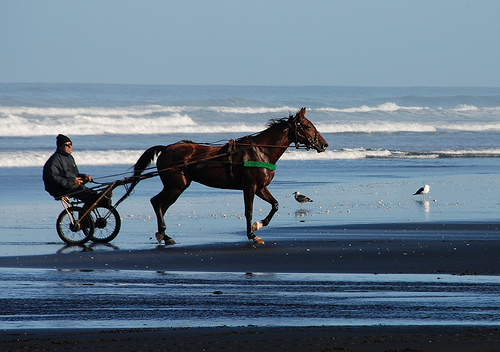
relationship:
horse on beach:
[132, 106, 330, 247] [1, 167, 499, 351]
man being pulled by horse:
[41, 132, 112, 229] [132, 106, 330, 247]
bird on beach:
[291, 190, 314, 207] [1, 167, 499, 351]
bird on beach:
[412, 182, 431, 196] [1, 167, 499, 351]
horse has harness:
[132, 106, 330, 247] [175, 114, 301, 171]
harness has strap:
[175, 114, 301, 171] [241, 159, 277, 172]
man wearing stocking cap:
[41, 132, 112, 229] [55, 131, 72, 147]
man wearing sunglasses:
[41, 132, 112, 229] [62, 141, 73, 148]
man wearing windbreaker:
[41, 132, 112, 229] [42, 150, 87, 194]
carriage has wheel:
[52, 179, 123, 244] [55, 205, 95, 246]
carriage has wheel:
[52, 179, 123, 244] [80, 201, 121, 243]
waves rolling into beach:
[1, 146, 499, 166] [1, 167, 499, 351]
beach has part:
[1, 167, 499, 351] [0, 326, 499, 351]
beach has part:
[1, 167, 499, 351] [0, 221, 499, 277]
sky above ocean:
[1, 1, 500, 88] [1, 82, 498, 169]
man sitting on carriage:
[41, 132, 112, 229] [52, 179, 123, 244]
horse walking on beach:
[132, 106, 330, 247] [1, 167, 499, 351]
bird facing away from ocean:
[412, 182, 431, 196] [1, 82, 498, 169]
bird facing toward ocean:
[291, 190, 314, 207] [1, 82, 498, 169]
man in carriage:
[41, 132, 112, 229] [52, 179, 123, 244]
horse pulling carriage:
[132, 106, 330, 247] [52, 179, 123, 244]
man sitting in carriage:
[41, 132, 112, 229] [52, 179, 123, 244]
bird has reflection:
[412, 182, 431, 196] [415, 199, 431, 215]